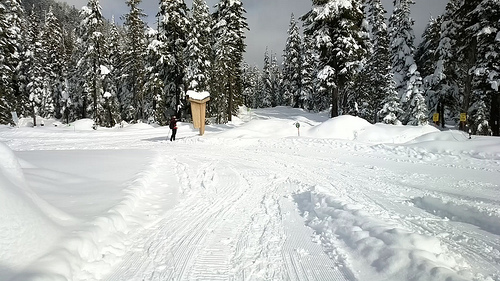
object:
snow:
[2, 126, 39, 145]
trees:
[80, 0, 149, 129]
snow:
[260, 108, 308, 118]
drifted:
[44, 151, 122, 216]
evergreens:
[150, 0, 196, 125]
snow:
[176, 204, 204, 226]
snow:
[306, 113, 372, 144]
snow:
[209, 151, 307, 174]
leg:
[169, 127, 177, 137]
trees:
[249, 45, 282, 108]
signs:
[432, 112, 439, 122]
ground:
[444, 90, 475, 132]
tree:
[157, 0, 249, 125]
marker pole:
[294, 121, 301, 137]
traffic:
[302, 139, 427, 206]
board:
[459, 112, 467, 122]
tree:
[340, 0, 432, 126]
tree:
[281, 11, 303, 108]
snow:
[221, 248, 302, 280]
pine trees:
[413, 0, 500, 135]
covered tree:
[0, 0, 71, 128]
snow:
[6, 145, 149, 275]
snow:
[217, 192, 272, 240]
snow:
[305, 144, 393, 178]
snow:
[475, 144, 500, 179]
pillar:
[190, 104, 208, 136]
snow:
[308, 183, 474, 279]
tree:
[296, 0, 371, 117]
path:
[101, 138, 499, 280]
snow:
[251, 146, 317, 199]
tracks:
[119, 161, 317, 279]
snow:
[5, 54, 132, 123]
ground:
[0, 106, 499, 280]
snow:
[380, 17, 431, 124]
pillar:
[437, 102, 445, 127]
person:
[169, 114, 182, 141]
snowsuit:
[168, 118, 177, 138]